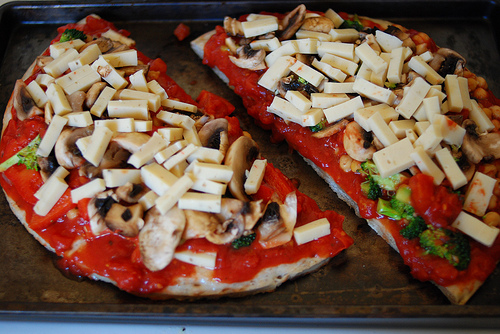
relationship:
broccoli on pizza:
[21, 141, 42, 171] [0, 12, 351, 302]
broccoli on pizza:
[232, 232, 257, 252] [0, 12, 351, 302]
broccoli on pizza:
[57, 26, 84, 46] [0, 12, 351, 302]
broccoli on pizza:
[223, 46, 233, 53] [190, 7, 500, 308]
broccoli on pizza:
[339, 11, 365, 32] [190, 7, 500, 308]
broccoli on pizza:
[291, 74, 306, 95] [190, 7, 500, 308]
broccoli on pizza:
[311, 118, 325, 135] [190, 7, 500, 308]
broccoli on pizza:
[360, 157, 405, 197] [190, 7, 500, 308]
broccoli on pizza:
[375, 180, 419, 228] [190, 7, 500, 308]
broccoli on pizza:
[404, 212, 426, 240] [190, 7, 500, 308]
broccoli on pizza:
[419, 224, 474, 272] [190, 7, 500, 308]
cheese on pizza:
[296, 220, 334, 242] [0, 12, 351, 302]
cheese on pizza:
[244, 161, 271, 190] [0, 12, 351, 302]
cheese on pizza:
[177, 191, 224, 213] [0, 12, 351, 302]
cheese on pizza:
[71, 178, 111, 197] [0, 12, 351, 302]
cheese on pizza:
[31, 111, 70, 159] [0, 12, 351, 302]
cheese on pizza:
[86, 127, 113, 162] [0, 12, 351, 302]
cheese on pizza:
[107, 97, 152, 119] [0, 12, 351, 302]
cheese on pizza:
[45, 83, 72, 116] [0, 12, 351, 302]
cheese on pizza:
[452, 207, 496, 243] [190, 7, 500, 308]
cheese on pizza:
[464, 165, 496, 217] [190, 7, 500, 308]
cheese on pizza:
[370, 134, 416, 179] [190, 7, 500, 308]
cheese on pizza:
[322, 94, 365, 122] [190, 7, 500, 308]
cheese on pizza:
[357, 39, 390, 81] [190, 7, 500, 308]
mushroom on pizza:
[98, 200, 141, 236] [0, 12, 351, 302]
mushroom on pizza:
[224, 130, 260, 203] [0, 12, 351, 302]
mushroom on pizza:
[12, 76, 43, 119] [0, 12, 351, 302]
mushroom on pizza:
[54, 126, 84, 165] [0, 12, 351, 302]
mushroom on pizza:
[198, 111, 230, 149] [0, 12, 351, 302]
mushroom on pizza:
[233, 46, 266, 67] [190, 7, 500, 308]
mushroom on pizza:
[434, 47, 466, 79] [190, 7, 500, 308]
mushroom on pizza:
[342, 125, 377, 158] [190, 7, 500, 308]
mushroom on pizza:
[279, 0, 306, 36] [190, 7, 500, 308]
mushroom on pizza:
[462, 118, 499, 162] [190, 7, 500, 308]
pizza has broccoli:
[0, 12, 351, 302] [232, 232, 257, 252]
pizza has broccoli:
[0, 12, 351, 302] [21, 141, 42, 171]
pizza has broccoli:
[190, 7, 500, 308] [360, 157, 405, 197]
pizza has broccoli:
[190, 7, 500, 308] [291, 74, 306, 95]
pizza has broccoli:
[190, 7, 500, 308] [404, 212, 426, 240]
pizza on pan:
[0, 12, 351, 302] [3, 3, 500, 317]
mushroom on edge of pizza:
[434, 47, 466, 79] [190, 7, 500, 308]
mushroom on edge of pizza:
[12, 76, 43, 119] [0, 12, 351, 302]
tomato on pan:
[169, 22, 193, 43] [3, 3, 500, 317]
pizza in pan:
[0, 12, 351, 302] [3, 3, 500, 317]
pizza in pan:
[190, 7, 500, 308] [3, 3, 500, 317]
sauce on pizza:
[0, 121, 337, 295] [0, 12, 351, 302]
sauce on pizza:
[205, 35, 456, 278] [190, 7, 500, 308]